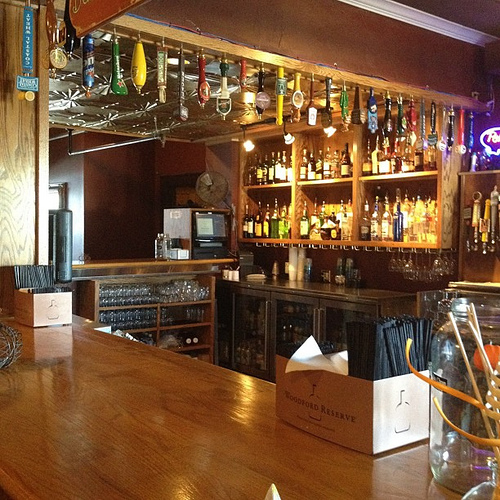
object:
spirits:
[392, 198, 404, 243]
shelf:
[357, 169, 439, 185]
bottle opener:
[176, 41, 190, 124]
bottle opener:
[154, 35, 168, 106]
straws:
[426, 320, 434, 362]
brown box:
[11, 284, 74, 329]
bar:
[0, 0, 499, 499]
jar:
[426, 276, 500, 499]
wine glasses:
[401, 251, 416, 283]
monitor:
[190, 208, 232, 244]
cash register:
[190, 209, 232, 260]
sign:
[477, 124, 499, 159]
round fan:
[194, 168, 231, 207]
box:
[273, 352, 430, 458]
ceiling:
[334, 0, 500, 51]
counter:
[0, 311, 499, 499]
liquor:
[359, 138, 373, 178]